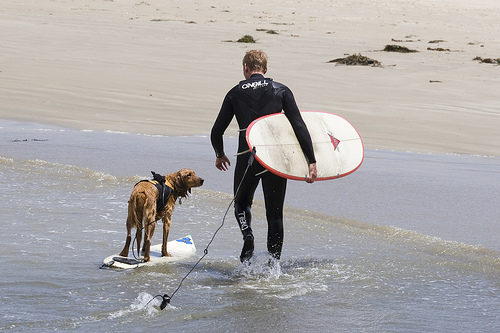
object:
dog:
[119, 168, 204, 262]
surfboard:
[103, 235, 196, 269]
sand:
[1, 2, 499, 332]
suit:
[210, 78, 318, 261]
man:
[210, 49, 316, 269]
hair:
[242, 49, 267, 73]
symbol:
[241, 80, 268, 91]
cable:
[142, 148, 258, 313]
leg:
[234, 155, 287, 270]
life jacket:
[135, 170, 174, 212]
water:
[5, 123, 496, 331]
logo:
[326, 133, 340, 152]